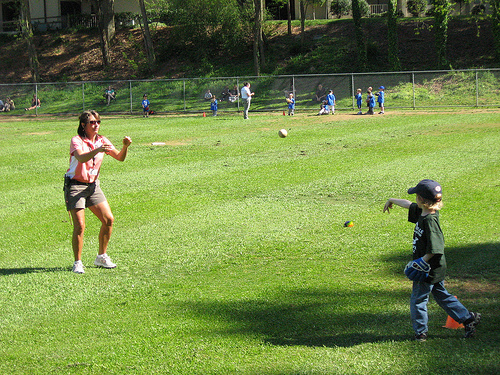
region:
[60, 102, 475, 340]
The mother is teaching her son how to throw a ball.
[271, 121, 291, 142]
A ball.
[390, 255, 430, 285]
A baseball glove is on the boy's left hand.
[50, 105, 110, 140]
The mother is wearing sunglasses.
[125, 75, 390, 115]
Kids are playing a game.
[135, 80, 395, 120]
All of the kids have blue t-shirts on.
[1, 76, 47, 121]
People are lying on the grass, in the shade.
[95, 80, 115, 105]
The woman is sitting in a chair.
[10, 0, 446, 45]
Homes are on top of the hill.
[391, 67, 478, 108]
A chain-link fence.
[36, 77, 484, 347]
mother and child playing catch in park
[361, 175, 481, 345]
child wearing mitt on left hand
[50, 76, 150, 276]
mother standing in position to catch ball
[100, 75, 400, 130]
team in uniform with coach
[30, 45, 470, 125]
fencing along the park border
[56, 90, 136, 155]
woman in shoulder length hair wearing sunglasses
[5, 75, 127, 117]
people seated outside of the fence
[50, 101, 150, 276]
woman with arms and legs bent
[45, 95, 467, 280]
pale green stripes along the width of the field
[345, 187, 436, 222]
boy's arm extended with hand pointed down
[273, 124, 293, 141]
a small athletic ball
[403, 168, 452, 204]
a child's baseball cap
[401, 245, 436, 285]
bright blue catching mit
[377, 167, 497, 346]
a small child throwing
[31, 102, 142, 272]
a woman waiting to catch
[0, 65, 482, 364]
a large grass field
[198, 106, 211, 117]
a small orange cone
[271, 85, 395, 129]
a group of small children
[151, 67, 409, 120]
a woman coaching children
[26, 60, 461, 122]
a chain link fence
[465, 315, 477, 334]
right sport shoe of the small boy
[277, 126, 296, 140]
a thrown baseball on air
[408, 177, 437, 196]
a navy blue cap on the small boy's head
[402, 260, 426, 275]
a baseball glove on the left hand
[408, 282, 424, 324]
section of one side of a jeans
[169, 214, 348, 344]
nicely cut levelised green grass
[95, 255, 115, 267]
left white sport shoes on the lady's leg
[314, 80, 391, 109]
other children in blue shirts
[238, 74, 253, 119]
a woman in a white top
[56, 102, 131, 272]
a woman in a pink shirt and a short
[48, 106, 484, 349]
adult and child playing catch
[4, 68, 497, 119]
a metal fence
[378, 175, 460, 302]
a child with a baseball glove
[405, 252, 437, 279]
a blue baseball glove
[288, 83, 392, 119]
a group of kids in blue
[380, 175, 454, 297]
a child wearing a black t-shirt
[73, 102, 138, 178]
a woman with her arms out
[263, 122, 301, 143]
a ball in the air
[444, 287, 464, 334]
a hidden orange cone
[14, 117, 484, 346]
a field of green grass